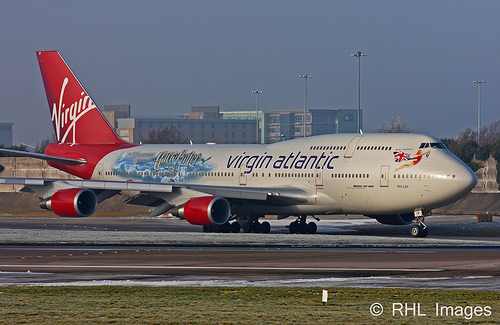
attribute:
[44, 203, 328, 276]
runway — concrete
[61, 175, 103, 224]
engine — red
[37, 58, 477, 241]
plane — virgin atlantic, jumbo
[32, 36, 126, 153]
tail — red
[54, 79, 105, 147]
letters — white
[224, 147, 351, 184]
logo — virgin atlantic, blue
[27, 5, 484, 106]
sky — blue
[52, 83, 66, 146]
letter — written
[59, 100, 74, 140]
letter — written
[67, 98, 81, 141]
letter — written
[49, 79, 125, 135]
logo — virgin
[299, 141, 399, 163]
windows — small